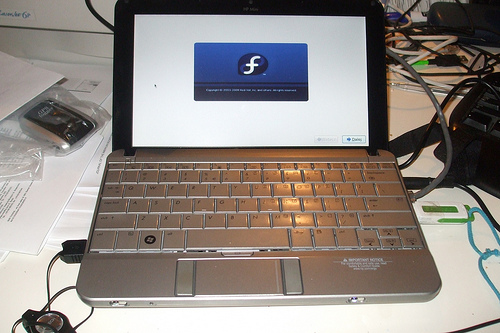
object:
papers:
[0, 117, 105, 256]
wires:
[386, 46, 454, 200]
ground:
[383, 184, 405, 209]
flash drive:
[412, 203, 477, 226]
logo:
[192, 41, 310, 101]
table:
[381, 22, 500, 330]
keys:
[302, 168, 322, 184]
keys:
[161, 228, 188, 251]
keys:
[262, 170, 281, 182]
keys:
[122, 182, 146, 199]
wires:
[395, 77, 500, 171]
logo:
[236, 52, 267, 77]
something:
[19, 238, 95, 331]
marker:
[411, 59, 429, 70]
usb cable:
[435, 52, 466, 68]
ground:
[391, 80, 455, 118]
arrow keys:
[381, 238, 402, 248]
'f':
[241, 54, 262, 77]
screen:
[109, 1, 389, 148]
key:
[171, 197, 190, 211]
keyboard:
[76, 149, 443, 309]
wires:
[387, 33, 475, 96]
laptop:
[74, 1, 443, 309]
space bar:
[185, 228, 293, 251]